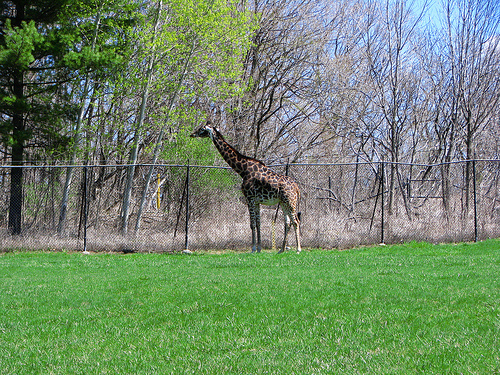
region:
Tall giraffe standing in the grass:
[186, 117, 305, 254]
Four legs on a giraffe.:
[245, 200, 305, 256]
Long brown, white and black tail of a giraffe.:
[296, 187, 303, 219]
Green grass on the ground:
[0, 245, 499, 374]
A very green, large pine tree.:
[0, 1, 144, 237]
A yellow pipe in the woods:
[154, 170, 161, 212]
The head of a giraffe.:
[186, 118, 215, 141]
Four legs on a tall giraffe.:
[245, 200, 302, 254]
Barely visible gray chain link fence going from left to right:
[1, 158, 499, 244]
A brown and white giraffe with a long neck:
[190, 123, 308, 255]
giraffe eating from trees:
[179, 111, 320, 254]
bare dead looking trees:
[346, 13, 435, 228]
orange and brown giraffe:
[180, 115, 315, 257]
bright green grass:
[55, 264, 238, 344]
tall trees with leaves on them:
[11, 14, 166, 242]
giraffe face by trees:
[189, 113, 213, 140]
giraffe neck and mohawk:
[211, 121, 268, 175]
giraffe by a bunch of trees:
[54, 43, 359, 318]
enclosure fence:
[313, 140, 455, 242]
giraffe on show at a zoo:
[65, 63, 377, 320]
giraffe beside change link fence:
[187, 116, 310, 248]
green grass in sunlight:
[119, 292, 352, 339]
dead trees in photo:
[351, 73, 438, 157]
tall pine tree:
[3, 7, 65, 240]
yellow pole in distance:
[150, 175, 167, 213]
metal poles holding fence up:
[170, 166, 197, 252]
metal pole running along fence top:
[2, 162, 180, 172]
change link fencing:
[3, 149, 213, 247]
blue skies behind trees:
[402, 6, 459, 29]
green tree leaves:
[6, 23, 209, 77]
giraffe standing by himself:
[179, 113, 323, 258]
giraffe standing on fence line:
[15, 115, 486, 257]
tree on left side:
[8, 2, 126, 247]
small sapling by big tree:
[138, 10, 250, 241]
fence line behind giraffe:
[3, 150, 483, 229]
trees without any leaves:
[250, 8, 499, 225]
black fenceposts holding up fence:
[63, 168, 493, 250]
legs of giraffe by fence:
[239, 193, 302, 253]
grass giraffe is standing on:
[5, 246, 495, 373]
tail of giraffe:
[294, 191, 310, 221]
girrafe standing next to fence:
[186, 103, 337, 260]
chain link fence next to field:
[22, 143, 473, 265]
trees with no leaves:
[264, 26, 473, 176]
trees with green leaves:
[14, 6, 195, 154]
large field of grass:
[28, 251, 495, 356]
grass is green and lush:
[33, 262, 469, 354]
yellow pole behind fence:
[147, 169, 177, 235]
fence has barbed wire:
[5, 144, 497, 174]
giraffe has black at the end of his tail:
[281, 182, 321, 242]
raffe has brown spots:
[213, 144, 310, 250]